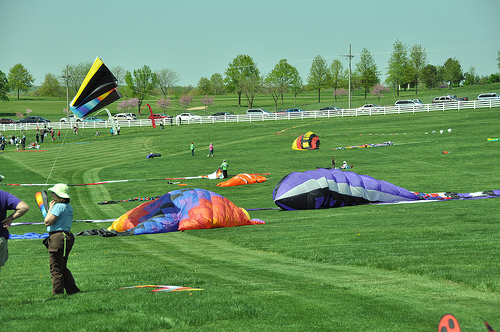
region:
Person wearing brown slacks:
[30, 176, 87, 306]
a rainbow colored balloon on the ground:
[95, 182, 266, 240]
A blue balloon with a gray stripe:
[268, 164, 497, 209]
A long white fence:
[0, 94, 498, 139]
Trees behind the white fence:
[1, 48, 498, 112]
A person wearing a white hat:
[30, 181, 79, 299]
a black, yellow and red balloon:
[291, 127, 323, 157]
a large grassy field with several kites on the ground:
[0, 75, 497, 330]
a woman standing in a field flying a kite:
[38, 175, 85, 298]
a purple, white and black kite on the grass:
[269, 165, 496, 212]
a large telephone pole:
[340, 39, 357, 119]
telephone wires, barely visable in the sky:
[349, 45, 498, 62]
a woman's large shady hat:
[46, 180, 71, 200]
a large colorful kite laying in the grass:
[68, 185, 266, 240]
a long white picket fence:
[0, 88, 497, 139]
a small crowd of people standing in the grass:
[1, 122, 125, 151]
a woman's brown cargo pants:
[46, 231, 83, 301]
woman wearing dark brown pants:
[43, 181, 81, 295]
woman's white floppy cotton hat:
[46, 181, 71, 198]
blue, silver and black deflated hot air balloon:
[271, 166, 498, 209]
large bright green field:
[0, 105, 499, 330]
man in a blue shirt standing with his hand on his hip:
[0, 173, 30, 268]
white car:
[176, 112, 201, 118]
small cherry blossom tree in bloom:
[176, 89, 195, 112]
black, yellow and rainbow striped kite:
[70, 55, 122, 120]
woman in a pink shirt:
[206, 142, 216, 157]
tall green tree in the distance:
[7, 61, 34, 98]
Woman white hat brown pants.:
[33, 178, 95, 312]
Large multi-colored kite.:
[95, 179, 268, 242]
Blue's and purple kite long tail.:
[269, 158, 499, 220]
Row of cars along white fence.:
[183, 87, 499, 119]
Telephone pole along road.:
[339, 39, 359, 121]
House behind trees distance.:
[392, 63, 477, 93]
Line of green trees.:
[209, 44, 340, 103]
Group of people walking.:
[1, 124, 108, 153]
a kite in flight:
[70, 55, 122, 120]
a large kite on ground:
[273, 162, 497, 209]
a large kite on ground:
[101, 185, 266, 230]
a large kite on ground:
[291, 129, 321, 150]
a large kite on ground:
[217, 170, 268, 186]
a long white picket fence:
[1, 96, 499, 131]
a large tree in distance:
[225, 53, 259, 104]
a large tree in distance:
[267, 58, 298, 105]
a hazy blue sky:
[1, 0, 498, 86]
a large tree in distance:
[6, 62, 34, 99]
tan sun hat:
[46, 178, 73, 205]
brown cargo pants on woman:
[41, 228, 83, 298]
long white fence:
[1, 93, 499, 135]